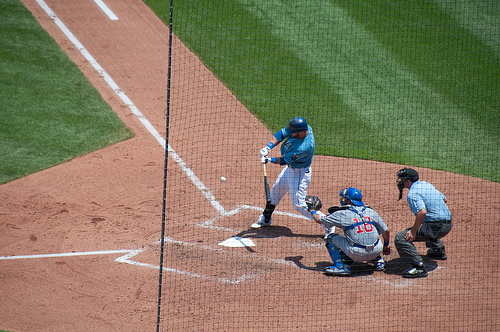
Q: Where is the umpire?
A: Behind the catcher.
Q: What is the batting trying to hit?
A: Ball.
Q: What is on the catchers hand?
A: Mit.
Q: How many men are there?
A: Three.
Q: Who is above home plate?
A: Batter.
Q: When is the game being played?
A: Daytime.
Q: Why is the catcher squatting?
A: To catch the ball.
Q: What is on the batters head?
A: Helmet.